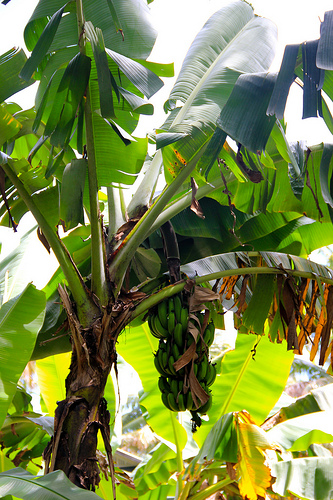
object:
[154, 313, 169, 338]
banana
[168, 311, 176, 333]
bananas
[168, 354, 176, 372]
bunch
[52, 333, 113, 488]
trunk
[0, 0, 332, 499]
tree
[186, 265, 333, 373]
leaves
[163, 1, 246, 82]
sun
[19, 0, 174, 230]
leaf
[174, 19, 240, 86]
sunlight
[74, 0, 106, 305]
stem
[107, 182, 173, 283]
branch